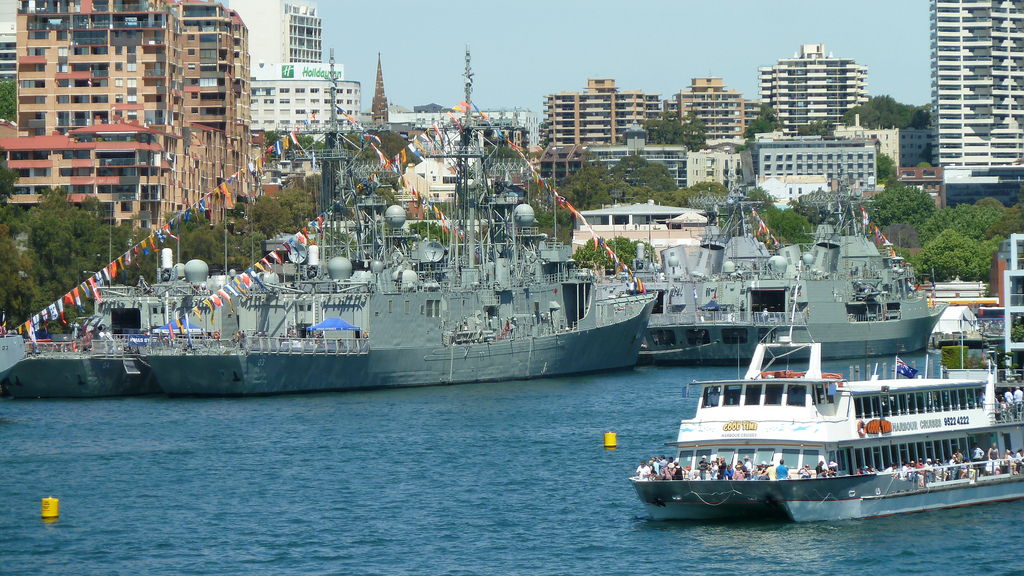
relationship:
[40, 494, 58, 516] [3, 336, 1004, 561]
item in water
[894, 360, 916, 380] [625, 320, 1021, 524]
flag near boat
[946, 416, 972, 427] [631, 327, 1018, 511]
letter on boat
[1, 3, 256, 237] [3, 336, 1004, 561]
building near water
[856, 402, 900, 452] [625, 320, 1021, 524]
logo on boat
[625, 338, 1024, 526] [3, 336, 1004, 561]
boat are on water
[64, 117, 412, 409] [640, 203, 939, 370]
ship docked near ship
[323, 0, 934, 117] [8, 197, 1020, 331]
blue sky above land